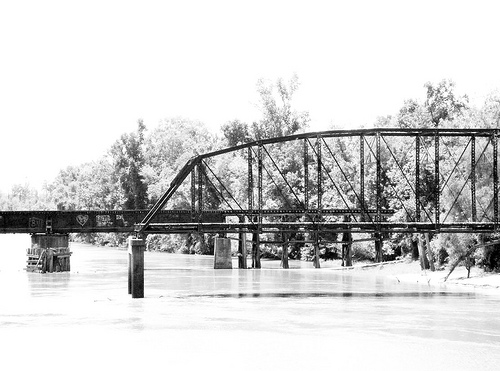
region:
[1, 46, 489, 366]
Picture taken in black and white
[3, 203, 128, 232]
worn out bridge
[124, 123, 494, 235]
Train trellis over water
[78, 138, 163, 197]
Trees along the riverbank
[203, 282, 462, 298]
shadow of bridge in the water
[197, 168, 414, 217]
Metal bars holding up the structure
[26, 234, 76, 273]
cement pillar in the water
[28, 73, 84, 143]
clear white sky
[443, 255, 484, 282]
branch hanging down into the water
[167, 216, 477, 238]
surface of the bridge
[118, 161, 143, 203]
a bunch of tree branches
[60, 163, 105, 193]
a bunch of snow on a tree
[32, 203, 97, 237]
the bridge on a river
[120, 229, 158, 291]
the leg of a bridge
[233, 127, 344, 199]
the fence on a bridge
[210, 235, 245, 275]
a large piece of stone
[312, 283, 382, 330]
a big frozen lake under a bridge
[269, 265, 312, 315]
the shadow of a bridge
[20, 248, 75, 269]
a bunch of wood pieces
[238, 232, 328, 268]
a fence made out of wood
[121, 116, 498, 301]
a bridge over the water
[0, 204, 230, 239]
the bridge is black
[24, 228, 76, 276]
a column under a bridge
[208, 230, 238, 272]
a column under a bridge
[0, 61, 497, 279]
trees on the shore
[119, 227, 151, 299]
a column on left side of bridge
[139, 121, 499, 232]
the rail of bridge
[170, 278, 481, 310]
the reflection of bridge on the water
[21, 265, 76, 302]
reflection of bridge on water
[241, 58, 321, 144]
the branch of a tree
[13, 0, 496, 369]
Black and white photo of train trestle bridge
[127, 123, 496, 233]
Metal trestle of bridge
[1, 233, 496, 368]
River underneath trestle bridge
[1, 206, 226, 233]
Freight train cars on trestle bridge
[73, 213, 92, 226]
Graffiti on freight train car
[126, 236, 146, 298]
Cement bridge support pylon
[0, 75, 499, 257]
Leaf covered trees on riverbank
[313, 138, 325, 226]
Metal support beam on bridge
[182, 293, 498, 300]
Shadow of bridge in river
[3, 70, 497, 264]
trees growing along the river bank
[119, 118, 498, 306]
antique metal, covered bridge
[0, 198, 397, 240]
metal bridge for trains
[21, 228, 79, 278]
large concrete bridge support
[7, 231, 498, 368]
wide river with bridges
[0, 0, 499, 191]
clear bright white sky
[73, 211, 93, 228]
spray painted white graffiti hear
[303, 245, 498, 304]
sandy river shore line